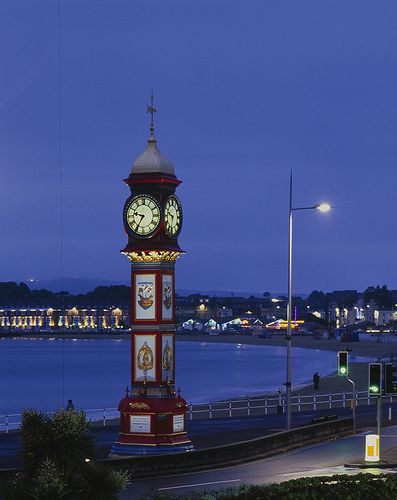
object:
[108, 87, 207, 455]
tower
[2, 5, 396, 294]
sky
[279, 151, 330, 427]
light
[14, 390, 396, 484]
road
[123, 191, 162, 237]
clock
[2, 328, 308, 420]
water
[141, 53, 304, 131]
sky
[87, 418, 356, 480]
boundary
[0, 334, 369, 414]
water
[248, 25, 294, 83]
sky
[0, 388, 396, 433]
fence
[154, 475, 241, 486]
line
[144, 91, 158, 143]
weather vane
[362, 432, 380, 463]
box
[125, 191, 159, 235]
face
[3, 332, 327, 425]
water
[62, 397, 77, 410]
person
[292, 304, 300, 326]
pole